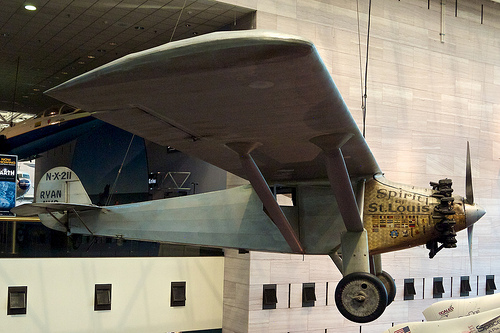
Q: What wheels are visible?
A: The front two.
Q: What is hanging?
A: An airplane model.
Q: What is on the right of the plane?
A: The wing.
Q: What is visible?
A: Two wheels.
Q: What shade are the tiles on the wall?
A: White.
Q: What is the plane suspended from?
A: Cables.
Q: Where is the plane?
A: In a museum.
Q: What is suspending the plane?
A: Wires.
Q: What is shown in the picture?
A: A plane.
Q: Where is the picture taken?
A: A museum.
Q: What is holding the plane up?
A: Wires.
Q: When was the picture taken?
A: At daytime.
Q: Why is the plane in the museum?
A: It's antique.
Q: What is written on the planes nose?
A: Spirit of St Louis.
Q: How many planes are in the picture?
A: Two.